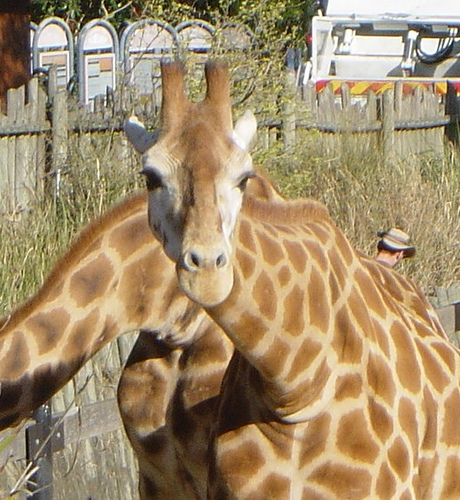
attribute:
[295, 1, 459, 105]
truck — large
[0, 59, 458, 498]
giraffe — large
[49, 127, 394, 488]
giraffes — brown, tan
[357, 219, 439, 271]
hat — tan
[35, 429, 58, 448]
screws — silver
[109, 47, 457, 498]
giraffe — large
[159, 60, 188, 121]
horn — furry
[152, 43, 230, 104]
horns — small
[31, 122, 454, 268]
grass — tall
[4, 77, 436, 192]
fence — wood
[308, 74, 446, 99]
stripe — yellow, red